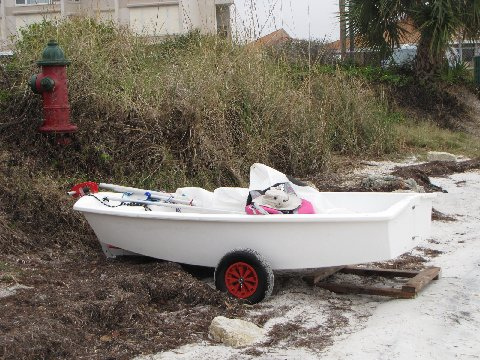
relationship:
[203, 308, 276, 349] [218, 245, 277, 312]
boulder near tire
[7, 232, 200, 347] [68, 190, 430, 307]
dirt near boat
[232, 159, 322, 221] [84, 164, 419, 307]
item in boat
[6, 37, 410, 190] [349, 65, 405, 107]
hill with plants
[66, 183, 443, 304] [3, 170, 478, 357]
boat on shore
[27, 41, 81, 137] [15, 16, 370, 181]
hydrant in grass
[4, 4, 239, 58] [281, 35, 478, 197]
building on beach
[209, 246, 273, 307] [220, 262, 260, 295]
wheels with rim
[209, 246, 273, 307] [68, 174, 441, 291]
wheels on trailer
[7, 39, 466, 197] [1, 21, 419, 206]
slope covered in grass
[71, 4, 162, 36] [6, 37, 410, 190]
building on hill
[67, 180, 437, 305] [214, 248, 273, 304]
dingy on wheel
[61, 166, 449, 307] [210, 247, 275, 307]
dingy has wheel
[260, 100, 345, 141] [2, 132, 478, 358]
seaweed piled on beach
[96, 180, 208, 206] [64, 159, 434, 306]
pole in boat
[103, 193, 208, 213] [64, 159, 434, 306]
pole in boat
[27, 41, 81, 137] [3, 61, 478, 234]
hydrant sitting on bank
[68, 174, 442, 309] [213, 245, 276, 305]
trailer has wheel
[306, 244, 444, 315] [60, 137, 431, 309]
wood under boat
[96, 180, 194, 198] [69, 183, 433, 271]
pole in boat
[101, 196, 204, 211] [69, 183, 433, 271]
poles in boat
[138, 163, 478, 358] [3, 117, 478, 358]
snow on ground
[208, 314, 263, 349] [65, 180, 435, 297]
rock next to boat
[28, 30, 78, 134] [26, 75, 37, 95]
hydrant has opening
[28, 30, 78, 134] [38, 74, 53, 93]
hydrant has opening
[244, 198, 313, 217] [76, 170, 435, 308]
stuff inside boat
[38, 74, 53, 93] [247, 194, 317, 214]
opening on top of stuff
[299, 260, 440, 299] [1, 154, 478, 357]
frame on ground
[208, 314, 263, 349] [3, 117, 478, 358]
rock on ground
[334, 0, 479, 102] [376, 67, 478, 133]
tree has bottom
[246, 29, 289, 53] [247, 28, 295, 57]
roof installed on roof